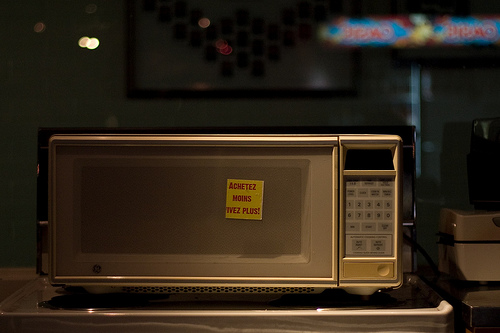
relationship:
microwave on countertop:
[36, 126, 417, 310] [1, 271, 456, 332]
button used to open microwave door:
[341, 260, 395, 282] [52, 139, 336, 279]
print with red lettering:
[225, 178, 263, 219] [227, 181, 261, 218]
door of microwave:
[50, 135, 338, 283] [36, 126, 417, 310]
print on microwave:
[225, 178, 263, 219] [36, 126, 417, 310]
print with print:
[225, 178, 263, 219] [224, 175, 262, 220]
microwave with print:
[46, 116, 413, 306] [225, 178, 263, 219]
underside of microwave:
[44, 276, 360, 310] [36, 126, 417, 310]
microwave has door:
[36, 126, 417, 310] [48, 135, 343, 285]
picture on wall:
[122, 31, 434, 103] [42, 40, 492, 148]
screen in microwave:
[341, 142, 398, 174] [36, 126, 417, 310]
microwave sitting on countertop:
[36, 126, 417, 310] [0, 277, 457, 331]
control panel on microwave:
[339, 174, 399, 257] [36, 126, 417, 310]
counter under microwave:
[0, 258, 453, 328] [36, 126, 417, 310]